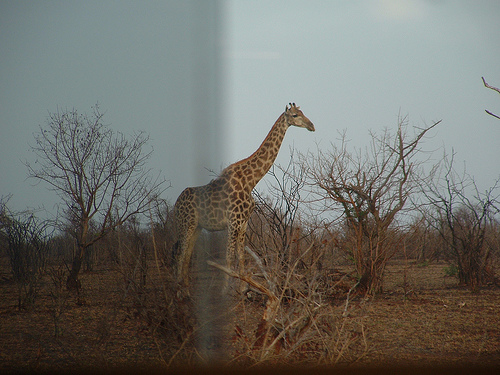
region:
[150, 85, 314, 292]
tan and brown spotted giraffe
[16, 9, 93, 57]
white clouds in blue sky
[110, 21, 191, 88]
white clouds in blue sky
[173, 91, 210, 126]
white clouds in blue sky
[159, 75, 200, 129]
white clouds in blue sky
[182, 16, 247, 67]
white clouds in blue sky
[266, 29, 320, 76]
white clouds in blue sky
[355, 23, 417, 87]
white clouds in blue sky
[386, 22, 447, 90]
white clouds in blue sky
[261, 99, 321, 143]
head of an giraffe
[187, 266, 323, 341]
brown tall bushes on ground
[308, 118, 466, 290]
tall brown pointy trees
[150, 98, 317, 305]
giraffe standing up straight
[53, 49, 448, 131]
gray sky no clouds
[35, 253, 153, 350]
brown dirt and leaves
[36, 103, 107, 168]
small brown leaves on tree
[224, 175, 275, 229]
giraffe has a pattern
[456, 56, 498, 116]
part of a tall tree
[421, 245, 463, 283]
small green bushes on ground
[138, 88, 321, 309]
spotted giraffe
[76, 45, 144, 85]
white clouds in blue sky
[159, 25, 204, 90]
white clouds in blue sky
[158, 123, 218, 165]
white clouds in blue sky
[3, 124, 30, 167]
white clouds in blue sky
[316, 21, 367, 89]
white clouds in blue sky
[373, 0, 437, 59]
white clouds in blue sky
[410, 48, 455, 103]
white clouds in blue sky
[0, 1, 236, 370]
The glass portion of the half opened window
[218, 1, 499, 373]
The open portion of the window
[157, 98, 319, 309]
The giraffe seen through the window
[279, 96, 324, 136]
The head of the giraffe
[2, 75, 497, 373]
The dead trees surrounding the giraffe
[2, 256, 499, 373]
The dirt covered ground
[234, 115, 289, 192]
The neck of the giraffe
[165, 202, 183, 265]
The tail of the giraffe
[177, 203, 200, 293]
The hind legs of the giraffe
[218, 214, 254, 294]
The front legs of the giraffe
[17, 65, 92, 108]
white clouds in blue sky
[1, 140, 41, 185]
white clouds in blue sky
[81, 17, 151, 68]
white clouds in blue sky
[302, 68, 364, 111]
white clouds in blue sky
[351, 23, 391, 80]
white clouds in blue sky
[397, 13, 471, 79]
white clouds in blue sky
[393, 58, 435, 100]
white clouds in blue sky